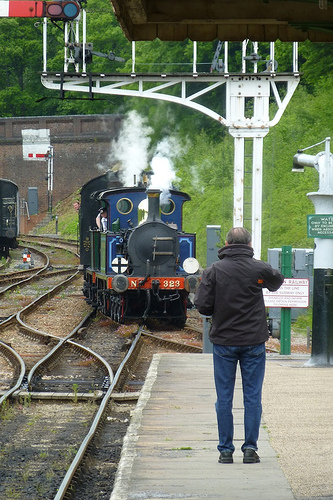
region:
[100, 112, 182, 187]
Steam coming from the train.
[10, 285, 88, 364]
Grass and gravels on the tracks.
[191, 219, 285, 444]
A man standing on the platform.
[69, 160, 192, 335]
A train on the tracks.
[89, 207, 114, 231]
A conductor on the train.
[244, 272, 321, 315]
A red and white sign on the green pole.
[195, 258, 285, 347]
The man is wearing a black jacket.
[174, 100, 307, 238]
The grass on the hill.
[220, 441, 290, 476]
The man is wearing black shoes.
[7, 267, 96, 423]
Sets of tracks on the ground.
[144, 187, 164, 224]
Smoke stack of a train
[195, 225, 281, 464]
A man standing next to train tracks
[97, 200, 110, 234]
Railroad engineer hanging out of a window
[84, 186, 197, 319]
A blue train's caboose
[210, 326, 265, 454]
Blue jeans on a man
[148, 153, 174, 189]
Smoke coming out of a smoke stack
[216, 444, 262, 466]
Black shoes on a standing man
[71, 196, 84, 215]
A man hanging his head out of a train window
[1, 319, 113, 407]
A pair of crisscrossing railroad tracks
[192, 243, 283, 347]
A man's black jacket being worn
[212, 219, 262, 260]
the head of a man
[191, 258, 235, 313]
the arm of a man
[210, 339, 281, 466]
the legs of a man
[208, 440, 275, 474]
the feet of a man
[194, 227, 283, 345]
a man wearing a coat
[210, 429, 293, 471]
a man wearing shoes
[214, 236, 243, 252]
the ear of a man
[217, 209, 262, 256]
the hair of a man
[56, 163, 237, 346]
a train on tracks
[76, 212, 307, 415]
a man near a train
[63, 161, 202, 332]
A man is looking out the train window.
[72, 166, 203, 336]
The man on the train is wearing a hat.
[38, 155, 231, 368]
The train is on the tracks.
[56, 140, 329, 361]
The tgrain is slowly approaching the station platform.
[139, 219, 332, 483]
The man is waiting on the platform.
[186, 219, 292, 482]
The man is wearing a jacket.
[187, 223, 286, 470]
The man is wearing blue jeans.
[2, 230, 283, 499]
The train tracks twist and curve in several directions.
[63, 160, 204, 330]
A man is looking out at the rear of the train.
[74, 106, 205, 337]
The train is expelling steam into the air.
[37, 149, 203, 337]
a locomotive traveling down the tracks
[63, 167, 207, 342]
a steam engine locomotive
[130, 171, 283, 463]
a man watching a locomotive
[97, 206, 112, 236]
the conductor of a train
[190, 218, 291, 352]
a man wearing a black jacket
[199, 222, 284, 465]
a man wearing bluejeans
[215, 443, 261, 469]
the black shoes of a man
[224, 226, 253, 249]
the head of a man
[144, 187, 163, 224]
the smoke stack on a locomotive